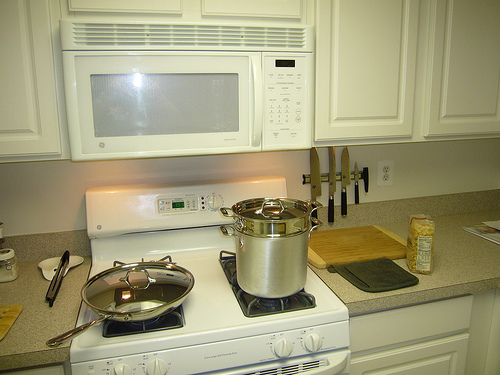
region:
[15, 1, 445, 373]
Kitchen in the home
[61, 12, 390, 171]
Over the counter white microwave oven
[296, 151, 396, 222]
Wall mounted knife holder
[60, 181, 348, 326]
Two stainless steel pots on the stove top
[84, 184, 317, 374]
White gas stove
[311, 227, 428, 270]
Wooden chopping board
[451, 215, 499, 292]
Beige laminated counter top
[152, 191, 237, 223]
Over timer and clock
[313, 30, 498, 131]
White kitchen cabinets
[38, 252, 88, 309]
White spoon rest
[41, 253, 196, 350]
pan with lid on stove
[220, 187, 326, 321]
large pot on stove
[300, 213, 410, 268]
wooden cutting board to right of stove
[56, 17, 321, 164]
white microwave oven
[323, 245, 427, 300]
black hot pad in front of cutting board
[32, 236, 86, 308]
knife to left of stove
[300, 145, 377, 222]
knives hanging on a wall rack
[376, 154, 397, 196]
electrical outlet on wall next to knife rack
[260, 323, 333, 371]
knobs to control stovetop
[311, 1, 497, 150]
white cabinets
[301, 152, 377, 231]
knives displayed on the wall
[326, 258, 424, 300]
a green pot holder on the counter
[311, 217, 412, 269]
a wooden cutting board on the counter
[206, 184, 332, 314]
a stainless steel double boiler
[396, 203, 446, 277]
a bag of pasta on the counter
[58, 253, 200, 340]
a silver frying pan with a lid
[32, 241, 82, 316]
a knife resting on a spoon rest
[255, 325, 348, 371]
white knobs on a stove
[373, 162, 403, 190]
electrical outlet on the wall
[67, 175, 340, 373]
a white stove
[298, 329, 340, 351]
button on white stove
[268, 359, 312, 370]
vent in the stove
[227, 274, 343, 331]
black burner on stove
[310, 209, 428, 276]
brown cutting board on counter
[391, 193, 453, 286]
brown bag on counter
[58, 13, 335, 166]
white microwave overhead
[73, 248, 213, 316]
silver skillet on stove top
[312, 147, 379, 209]
rack of knives on wall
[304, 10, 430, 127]
white doors on cabinet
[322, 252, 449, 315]
gray pot holder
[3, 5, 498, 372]
this is a kithen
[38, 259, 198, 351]
that is a frying pan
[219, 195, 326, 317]
this is a cooking pot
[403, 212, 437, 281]
a loaf of bread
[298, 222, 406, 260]
that is chopping board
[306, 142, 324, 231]
that is a kitchen knife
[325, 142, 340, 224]
that is a kitchen knife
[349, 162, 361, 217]
that is a kitchen knife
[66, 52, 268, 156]
that is a microwave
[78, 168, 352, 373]
an electric cooker in the kitchen